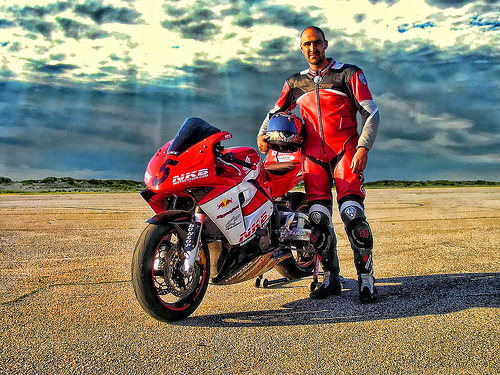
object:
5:
[152, 159, 179, 187]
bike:
[131, 119, 337, 319]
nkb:
[238, 210, 268, 242]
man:
[253, 28, 389, 300]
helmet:
[266, 112, 302, 154]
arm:
[256, 84, 291, 135]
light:
[74, 52, 97, 69]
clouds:
[136, 0, 166, 40]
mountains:
[0, 174, 17, 195]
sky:
[1, 0, 493, 33]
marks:
[189, 271, 496, 329]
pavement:
[2, 187, 496, 373]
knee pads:
[341, 199, 371, 252]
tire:
[130, 218, 209, 322]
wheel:
[272, 191, 322, 278]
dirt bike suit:
[268, 61, 380, 284]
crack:
[1, 281, 70, 310]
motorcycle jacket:
[256, 61, 379, 181]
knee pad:
[307, 204, 335, 264]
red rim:
[151, 230, 208, 310]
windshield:
[169, 116, 228, 152]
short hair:
[299, 26, 325, 39]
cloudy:
[2, 2, 499, 41]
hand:
[257, 135, 271, 154]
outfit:
[259, 60, 385, 302]